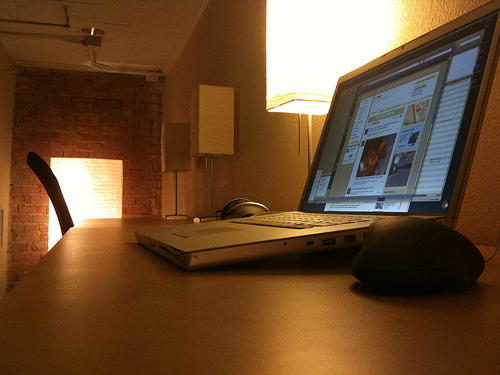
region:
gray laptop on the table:
[133, 1, 499, 268]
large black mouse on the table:
[350, 213, 486, 292]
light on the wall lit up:
[259, 19, 391, 116]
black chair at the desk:
[23, 154, 75, 235]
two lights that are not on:
[158, 85, 243, 217]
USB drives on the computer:
[319, 228, 371, 247]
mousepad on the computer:
[174, 222, 239, 240]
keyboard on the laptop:
[231, 205, 372, 229]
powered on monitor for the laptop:
[300, 20, 499, 220]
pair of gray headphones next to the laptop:
[213, 195, 270, 220]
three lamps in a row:
[117, 0, 427, 237]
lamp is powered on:
[227, 2, 388, 172]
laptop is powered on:
[142, 0, 498, 280]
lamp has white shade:
[172, 68, 248, 157]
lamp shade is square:
[173, 51, 247, 168]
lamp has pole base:
[175, 76, 244, 228]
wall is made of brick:
[20, 65, 160, 166]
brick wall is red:
[22, 84, 152, 155]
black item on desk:
[324, 190, 497, 347]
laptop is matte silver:
[126, 0, 490, 293]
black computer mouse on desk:
[363, 213, 475, 291]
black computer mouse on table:
[352, 210, 482, 288]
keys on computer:
[255, 203, 337, 233]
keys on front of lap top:
[245, 197, 343, 230]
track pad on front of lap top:
[172, 219, 240, 240]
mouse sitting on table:
[211, 190, 268, 218]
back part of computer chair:
[23, 150, 86, 237]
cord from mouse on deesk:
[490, 248, 498, 263]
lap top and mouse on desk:
[121, 14, 495, 289]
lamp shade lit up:
[272, 8, 340, 116]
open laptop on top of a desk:
[135, 0, 499, 270]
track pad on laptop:
[194, 225, 236, 242]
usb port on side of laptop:
[318, 236, 337, 247]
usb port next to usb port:
[343, 233, 359, 243]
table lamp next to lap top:
[265, 0, 336, 170]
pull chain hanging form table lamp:
[296, 110, 304, 150]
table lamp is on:
[264, 0, 349, 172]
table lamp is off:
[188, 84, 238, 221]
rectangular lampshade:
[188, 83, 238, 158]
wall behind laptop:
[158, 0, 498, 245]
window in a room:
[30, 147, 137, 250]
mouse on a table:
[348, 201, 485, 304]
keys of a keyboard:
[253, 200, 352, 224]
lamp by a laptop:
[248, 56, 344, 127]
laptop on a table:
[136, 4, 496, 282]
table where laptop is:
[52, 289, 339, 357]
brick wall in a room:
[17, 170, 46, 256]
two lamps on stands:
[147, 80, 239, 219]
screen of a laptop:
[353, 78, 458, 192]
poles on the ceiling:
[66, 50, 186, 82]